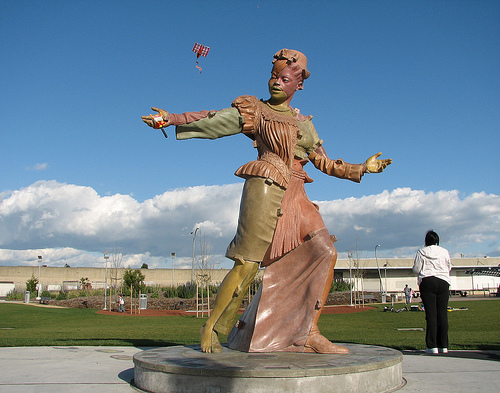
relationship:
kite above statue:
[193, 43, 210, 57] [141, 47, 394, 355]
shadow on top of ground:
[126, 338, 181, 347] [1, 343, 497, 392]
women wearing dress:
[141, 47, 394, 355] [232, 95, 335, 358]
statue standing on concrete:
[141, 47, 394, 355] [132, 342, 405, 392]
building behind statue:
[0, 268, 498, 295] [141, 47, 394, 355]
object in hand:
[154, 117, 167, 137] [142, 107, 175, 128]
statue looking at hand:
[141, 47, 394, 355] [142, 107, 175, 128]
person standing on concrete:
[412, 230, 453, 355] [1, 343, 497, 392]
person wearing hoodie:
[412, 230, 453, 355] [412, 246, 453, 285]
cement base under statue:
[132, 342, 405, 392] [141, 47, 394, 355]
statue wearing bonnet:
[141, 47, 394, 355] [271, 48, 310, 79]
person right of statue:
[412, 230, 453, 355] [141, 47, 394, 355]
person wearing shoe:
[412, 230, 453, 355] [427, 348, 438, 353]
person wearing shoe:
[412, 230, 453, 355] [441, 349, 449, 353]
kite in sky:
[193, 43, 210, 57] [2, 1, 498, 262]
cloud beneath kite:
[0, 181, 499, 256] [193, 43, 210, 57]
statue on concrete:
[141, 47, 394, 355] [132, 342, 405, 392]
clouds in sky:
[0, 181, 499, 256] [2, 1, 498, 262]